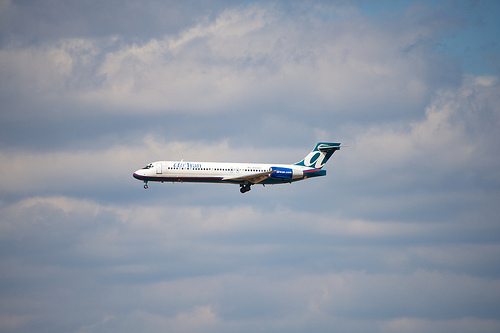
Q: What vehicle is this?
A: Plane.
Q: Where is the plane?
A: In the air.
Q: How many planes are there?
A: One.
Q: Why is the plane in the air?
A: It is flying.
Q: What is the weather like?
A: Partly cloudy.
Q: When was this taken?
A: During the day.